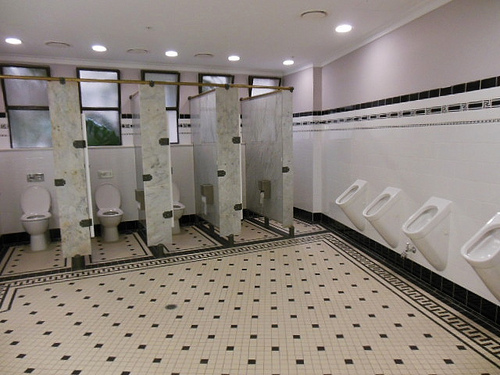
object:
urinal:
[460, 213, 500, 304]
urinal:
[401, 198, 452, 271]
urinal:
[362, 187, 403, 248]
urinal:
[334, 179, 366, 232]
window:
[81, 110, 121, 147]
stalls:
[239, 89, 283, 242]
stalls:
[166, 84, 219, 245]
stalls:
[81, 79, 147, 262]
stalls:
[0, 79, 60, 274]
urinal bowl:
[336, 186, 361, 206]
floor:
[0, 262, 500, 374]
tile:
[407, 313, 416, 318]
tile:
[409, 345, 420, 351]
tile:
[253, 298, 259, 302]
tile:
[184, 299, 191, 303]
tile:
[206, 335, 215, 339]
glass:
[8, 107, 51, 147]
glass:
[2, 64, 48, 106]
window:
[0, 66, 49, 107]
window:
[142, 69, 178, 106]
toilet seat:
[19, 212, 52, 221]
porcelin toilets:
[0, 150, 59, 270]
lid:
[19, 185, 51, 213]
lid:
[95, 183, 120, 210]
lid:
[172, 182, 180, 203]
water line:
[401, 242, 416, 259]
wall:
[281, 0, 499, 337]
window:
[75, 68, 119, 108]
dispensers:
[200, 184, 213, 205]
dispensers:
[134, 189, 145, 210]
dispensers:
[258, 179, 271, 199]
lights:
[282, 60, 293, 65]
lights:
[228, 55, 241, 61]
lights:
[163, 50, 177, 57]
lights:
[92, 45, 107, 53]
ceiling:
[4, 0, 449, 69]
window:
[164, 109, 179, 144]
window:
[200, 75, 234, 93]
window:
[250, 76, 280, 97]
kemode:
[19, 186, 51, 252]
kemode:
[94, 182, 124, 242]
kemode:
[172, 179, 184, 234]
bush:
[86, 119, 122, 145]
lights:
[4, 37, 22, 45]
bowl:
[27, 214, 46, 221]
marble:
[129, 89, 175, 247]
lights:
[334, 23, 352, 33]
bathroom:
[2, 4, 497, 375]